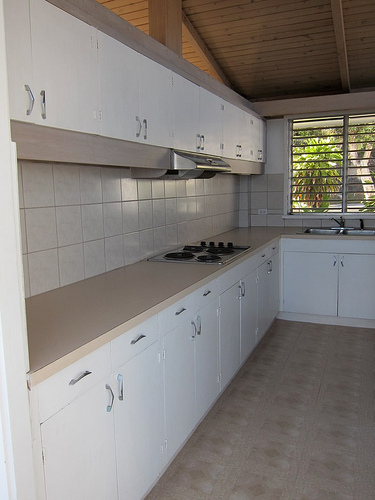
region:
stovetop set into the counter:
[146, 241, 251, 265]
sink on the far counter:
[299, 217, 374, 240]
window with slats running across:
[286, 109, 373, 213]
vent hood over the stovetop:
[131, 147, 231, 181]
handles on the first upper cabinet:
[24, 83, 48, 119]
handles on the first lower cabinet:
[101, 373, 125, 410]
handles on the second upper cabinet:
[134, 115, 149, 138]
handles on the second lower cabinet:
[190, 316, 202, 338]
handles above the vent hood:
[195, 131, 206, 149]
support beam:
[147, 0, 183, 58]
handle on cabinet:
[24, 83, 35, 114]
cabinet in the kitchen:
[282, 251, 373, 316]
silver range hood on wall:
[172, 152, 234, 172]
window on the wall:
[287, 115, 343, 214]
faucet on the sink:
[328, 215, 350, 228]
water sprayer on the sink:
[358, 218, 365, 226]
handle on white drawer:
[68, 369, 97, 385]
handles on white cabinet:
[330, 253, 350, 265]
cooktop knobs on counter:
[201, 238, 240, 248]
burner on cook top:
[161, 250, 192, 261]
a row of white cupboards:
[16, 35, 274, 170]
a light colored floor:
[230, 365, 364, 491]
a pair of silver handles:
[102, 373, 128, 409]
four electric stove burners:
[147, 240, 241, 267]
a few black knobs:
[197, 239, 233, 249]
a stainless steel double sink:
[300, 220, 373, 237]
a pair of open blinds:
[288, 115, 374, 218]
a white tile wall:
[22, 172, 244, 257]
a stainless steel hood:
[168, 151, 232, 178]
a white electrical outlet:
[254, 206, 270, 215]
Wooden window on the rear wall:
[281, 108, 374, 225]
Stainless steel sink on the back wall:
[294, 223, 373, 240]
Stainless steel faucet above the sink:
[327, 213, 351, 230]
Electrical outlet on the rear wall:
[255, 204, 270, 217]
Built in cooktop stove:
[144, 239, 255, 268]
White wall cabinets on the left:
[0, 1, 267, 178]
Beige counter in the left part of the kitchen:
[19, 223, 310, 389]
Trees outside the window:
[290, 120, 374, 212]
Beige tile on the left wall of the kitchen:
[16, 150, 241, 300]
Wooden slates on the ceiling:
[94, 0, 374, 105]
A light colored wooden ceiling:
[94, 0, 373, 103]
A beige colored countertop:
[24, 224, 373, 388]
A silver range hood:
[130, 147, 232, 181]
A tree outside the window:
[290, 137, 345, 210]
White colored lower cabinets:
[27, 238, 373, 499]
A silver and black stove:
[147, 239, 252, 267]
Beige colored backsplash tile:
[16, 156, 374, 298]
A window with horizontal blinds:
[287, 107, 373, 214]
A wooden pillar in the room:
[146, 0, 186, 61]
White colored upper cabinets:
[3, 0, 267, 166]